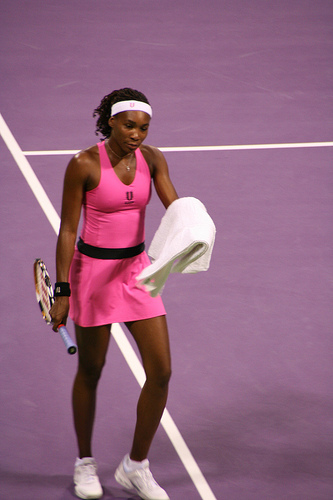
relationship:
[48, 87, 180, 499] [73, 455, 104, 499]
girl wearing sneaker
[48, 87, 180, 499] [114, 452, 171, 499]
girl wearing sneaker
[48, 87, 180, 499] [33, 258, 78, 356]
girl carrying tennis racquet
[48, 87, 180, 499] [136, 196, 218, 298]
girl carrying towel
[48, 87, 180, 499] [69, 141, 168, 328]
girl wearing dress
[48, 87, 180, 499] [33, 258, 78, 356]
girl carrying racket